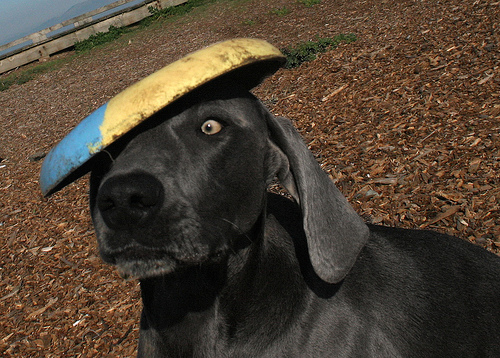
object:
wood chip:
[435, 190, 458, 202]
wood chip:
[322, 84, 350, 102]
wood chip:
[447, 46, 460, 52]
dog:
[90, 90, 500, 357]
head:
[85, 92, 371, 284]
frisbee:
[38, 37, 285, 201]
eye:
[198, 116, 226, 134]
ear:
[263, 107, 370, 283]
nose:
[96, 169, 164, 230]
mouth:
[100, 241, 232, 269]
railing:
[0, 0, 194, 75]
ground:
[0, 0, 500, 356]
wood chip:
[24, 296, 58, 322]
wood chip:
[114, 323, 135, 345]